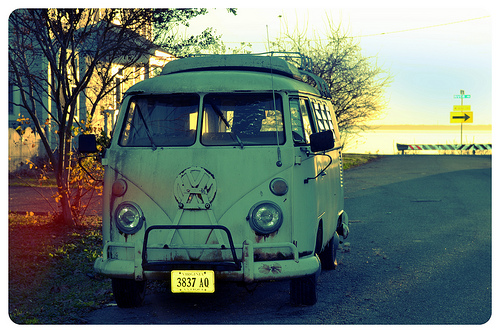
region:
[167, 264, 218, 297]
A yellow license plate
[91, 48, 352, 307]
The small bus is white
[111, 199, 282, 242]
Two headlights are round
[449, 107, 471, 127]
Black arrow pointing right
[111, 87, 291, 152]
Front windows on the bus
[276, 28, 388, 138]
Leaves on a tree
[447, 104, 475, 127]
An arrow on a yellow sign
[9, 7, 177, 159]
A house in the background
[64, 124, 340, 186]
Two side mirrors on the bus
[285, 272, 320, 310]
A black rubber tire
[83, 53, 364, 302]
vehicle on the road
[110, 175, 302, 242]
lights on the vehicle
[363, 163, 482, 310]
road where vehicles travel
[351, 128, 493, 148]
water near the road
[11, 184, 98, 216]
walkway near the home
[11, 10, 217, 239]
tree on the side of road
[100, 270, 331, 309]
front tires of the vehicle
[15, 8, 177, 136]
home on the side of road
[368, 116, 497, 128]
land on opposite side of water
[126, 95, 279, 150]
windows of the vehicle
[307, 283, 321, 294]
part of a wheel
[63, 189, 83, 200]
part of a stem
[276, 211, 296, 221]
part of a light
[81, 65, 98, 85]
part of a house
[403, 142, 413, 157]
part of a road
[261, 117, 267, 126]
part of a window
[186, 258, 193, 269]
edge of a truck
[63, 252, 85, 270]
part of a flower bed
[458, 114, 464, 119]
part of a post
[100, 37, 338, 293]
Teal colored van on pavement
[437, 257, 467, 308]
Small part of black pavement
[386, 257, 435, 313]
Small part of black pavement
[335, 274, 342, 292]
Small part of black pavement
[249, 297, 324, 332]
Small part of black pavement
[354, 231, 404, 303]
Small part of black pavement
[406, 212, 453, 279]
Small part of black pavement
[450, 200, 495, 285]
Small part of black pavement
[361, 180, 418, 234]
Small part of black pavement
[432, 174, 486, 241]
Small part of black pavement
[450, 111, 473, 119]
A yellow street sign.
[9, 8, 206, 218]
A tree on the sidewalk.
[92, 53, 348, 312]
A vehicle on the road.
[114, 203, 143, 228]
A head light of a vehicle.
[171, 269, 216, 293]
A number plate on a vehicle.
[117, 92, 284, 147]
Front windows of a vehicle.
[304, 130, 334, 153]
A rear mirror on a vehicle.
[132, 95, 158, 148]
A window wiper.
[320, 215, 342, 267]
A rear wheel on a vehicle.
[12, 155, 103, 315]
A paved sidewalk.